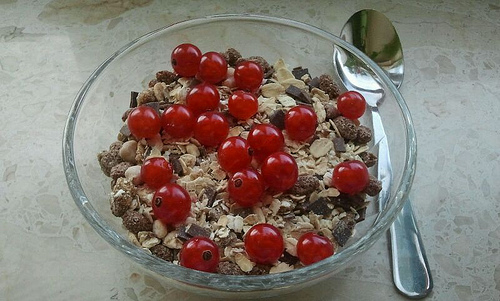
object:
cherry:
[130, 108, 157, 140]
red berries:
[217, 123, 296, 207]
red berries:
[127, 82, 228, 146]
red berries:
[141, 157, 191, 222]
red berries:
[228, 62, 265, 120]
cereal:
[329, 119, 378, 162]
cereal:
[270, 58, 315, 100]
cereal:
[191, 190, 228, 234]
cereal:
[98, 141, 141, 216]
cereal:
[221, 223, 244, 272]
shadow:
[47, 16, 244, 58]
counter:
[399, 61, 499, 201]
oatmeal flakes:
[97, 48, 381, 273]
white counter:
[1, 4, 498, 295]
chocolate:
[282, 75, 309, 97]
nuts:
[115, 50, 382, 276]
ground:
[461, 120, 481, 157]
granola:
[96, 47, 383, 275]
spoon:
[333, 7, 435, 298]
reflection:
[332, 22, 357, 97]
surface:
[0, 0, 499, 300]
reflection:
[345, 15, 404, 75]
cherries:
[262, 153, 294, 188]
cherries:
[220, 144, 247, 167]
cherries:
[155, 182, 186, 222]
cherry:
[243, 222, 284, 264]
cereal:
[100, 42, 380, 274]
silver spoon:
[363, 195, 439, 287]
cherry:
[331, 152, 377, 191]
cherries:
[125, 41, 370, 273]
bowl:
[62, 10, 419, 299]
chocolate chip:
[182, 220, 214, 240]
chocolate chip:
[294, 170, 318, 199]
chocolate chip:
[284, 84, 314, 104]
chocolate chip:
[145, 96, 166, 114]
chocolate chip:
[289, 57, 311, 79]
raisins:
[150, 241, 181, 260]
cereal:
[280, 123, 337, 242]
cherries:
[167, 31, 297, 206]